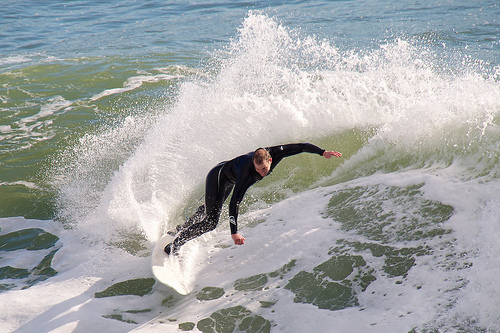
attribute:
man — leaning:
[164, 145, 342, 261]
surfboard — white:
[147, 201, 220, 298]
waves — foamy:
[2, 49, 210, 206]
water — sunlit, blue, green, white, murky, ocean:
[3, 3, 498, 332]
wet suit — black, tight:
[166, 144, 325, 248]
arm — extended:
[278, 141, 343, 160]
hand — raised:
[231, 233, 248, 248]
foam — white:
[1, 165, 499, 327]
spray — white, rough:
[30, 9, 500, 241]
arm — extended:
[226, 178, 243, 245]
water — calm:
[1, 5, 229, 54]